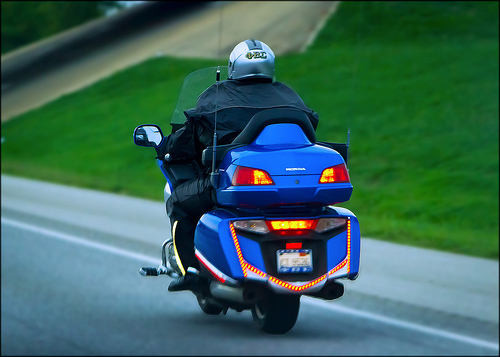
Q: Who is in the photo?
A: A person.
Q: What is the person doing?
A: Riding a motorcycle.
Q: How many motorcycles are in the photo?
A: One.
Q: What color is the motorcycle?
A: Blue.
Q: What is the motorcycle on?
A: The road.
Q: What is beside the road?
A: A hill.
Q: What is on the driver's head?
A: A helmet.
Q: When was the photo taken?
A: During the day.